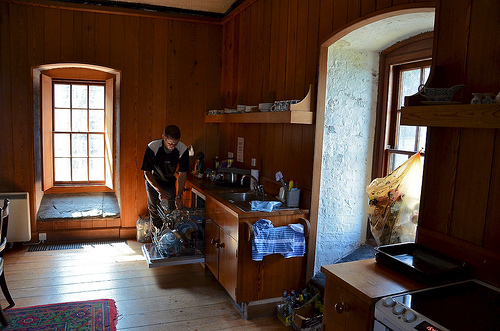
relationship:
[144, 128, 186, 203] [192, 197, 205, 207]
man over dishwasher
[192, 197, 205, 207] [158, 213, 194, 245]
dishwasher has dishes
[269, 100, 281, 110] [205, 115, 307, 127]
cup on cupboard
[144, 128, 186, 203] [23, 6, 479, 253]
man in kitchen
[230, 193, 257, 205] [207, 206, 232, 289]
sink above cabinet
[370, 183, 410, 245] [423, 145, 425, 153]
trash on nail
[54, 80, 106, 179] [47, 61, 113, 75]
window has arch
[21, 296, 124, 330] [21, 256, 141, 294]
rug on floor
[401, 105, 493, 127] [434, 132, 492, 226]
shelf on wall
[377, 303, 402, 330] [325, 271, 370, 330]
stove next to cabinet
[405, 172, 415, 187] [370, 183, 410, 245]
bag with trash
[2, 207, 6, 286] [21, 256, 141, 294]
chair on floor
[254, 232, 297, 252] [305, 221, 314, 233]
towel on rack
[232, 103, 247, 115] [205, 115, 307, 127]
dishes on cupboard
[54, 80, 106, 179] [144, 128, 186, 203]
window behind man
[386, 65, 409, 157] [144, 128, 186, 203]
window near man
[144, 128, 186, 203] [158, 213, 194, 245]
man putting up dishes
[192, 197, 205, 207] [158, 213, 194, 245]
dishwasher with dishes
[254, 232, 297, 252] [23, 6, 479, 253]
towel in kitchen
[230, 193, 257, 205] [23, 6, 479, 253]
sink in kitchen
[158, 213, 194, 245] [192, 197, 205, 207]
dishes in dishwasher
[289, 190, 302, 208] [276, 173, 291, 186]
container with utensils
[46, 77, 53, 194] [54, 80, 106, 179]
wood around window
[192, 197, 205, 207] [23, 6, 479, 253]
dishwasher in kitchen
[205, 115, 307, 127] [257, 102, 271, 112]
cupboard has bowls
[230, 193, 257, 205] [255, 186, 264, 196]
sink has faucet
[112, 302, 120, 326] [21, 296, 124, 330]
fringe on rug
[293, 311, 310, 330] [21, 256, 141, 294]
box on floor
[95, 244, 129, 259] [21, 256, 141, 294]
sunlight on floor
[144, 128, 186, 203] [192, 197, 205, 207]
man next to dishwasher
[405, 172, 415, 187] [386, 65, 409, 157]
bag on window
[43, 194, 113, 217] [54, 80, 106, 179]
spot by window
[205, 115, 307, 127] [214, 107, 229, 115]
cupboard with plates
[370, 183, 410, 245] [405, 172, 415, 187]
trash in bag